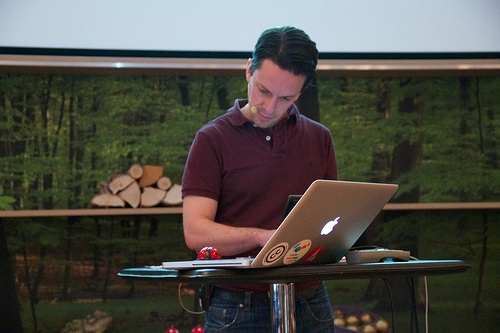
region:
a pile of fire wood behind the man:
[91, 163, 182, 208]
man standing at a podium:
[183, 26, 333, 331]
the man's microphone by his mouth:
[248, 91, 258, 115]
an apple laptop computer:
[162, 178, 397, 270]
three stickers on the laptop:
[265, 240, 322, 265]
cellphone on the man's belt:
[196, 279, 213, 310]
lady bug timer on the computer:
[194, 247, 221, 259]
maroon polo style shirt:
[182, 98, 336, 283]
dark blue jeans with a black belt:
[202, 289, 328, 331]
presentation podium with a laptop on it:
[123, 257, 468, 329]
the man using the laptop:
[178, 27, 358, 272]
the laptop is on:
[150, 177, 407, 284]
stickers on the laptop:
[272, 236, 320, 267]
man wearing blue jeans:
[203, 281, 319, 331]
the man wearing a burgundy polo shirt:
[207, 102, 334, 258]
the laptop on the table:
[161, 183, 409, 270]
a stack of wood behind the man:
[78, 165, 194, 213]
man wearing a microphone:
[240, 57, 258, 130]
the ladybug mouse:
[192, 238, 217, 257]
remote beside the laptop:
[340, 240, 420, 266]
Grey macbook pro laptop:
[258, 147, 392, 273]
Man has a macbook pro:
[155, 166, 390, 278]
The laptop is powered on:
[147, 175, 389, 280]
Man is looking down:
[232, 25, 325, 127]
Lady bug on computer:
[192, 236, 227, 264]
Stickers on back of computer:
[245, 224, 337, 269]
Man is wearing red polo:
[187, 90, 339, 222]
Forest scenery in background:
[5, 70, 498, 324]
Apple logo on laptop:
[315, 207, 345, 244]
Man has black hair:
[246, 17, 331, 91]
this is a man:
[198, 25, 339, 178]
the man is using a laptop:
[205, 23, 327, 168]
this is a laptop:
[280, 168, 395, 242]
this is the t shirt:
[225, 129, 295, 184]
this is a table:
[260, 267, 285, 284]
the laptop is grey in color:
[303, 178, 353, 206]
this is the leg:
[270, 284, 295, 328]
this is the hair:
[280, 28, 312, 65]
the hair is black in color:
[285, 28, 313, 67]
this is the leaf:
[44, 85, 132, 142]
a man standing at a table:
[127, 22, 380, 297]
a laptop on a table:
[161, 174, 388, 301]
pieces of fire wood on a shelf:
[78, 150, 171, 221]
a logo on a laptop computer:
[312, 195, 353, 244]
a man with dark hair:
[254, 26, 341, 78]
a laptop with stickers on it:
[262, 234, 357, 266]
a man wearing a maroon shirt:
[199, 80, 325, 214]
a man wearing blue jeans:
[215, 289, 345, 323]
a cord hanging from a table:
[410, 267, 437, 331]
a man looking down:
[235, 29, 316, 193]